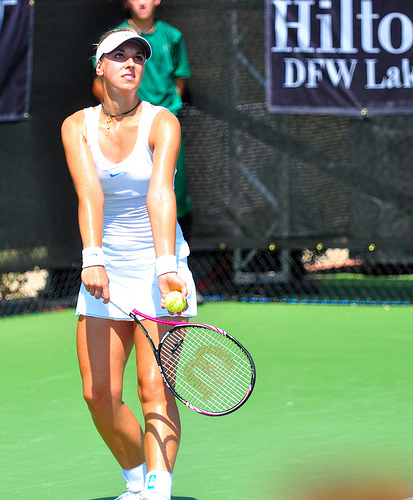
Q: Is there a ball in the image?
A: Yes, there is a ball.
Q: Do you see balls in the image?
A: Yes, there is a ball.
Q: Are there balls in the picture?
A: Yes, there is a ball.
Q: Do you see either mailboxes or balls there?
A: Yes, there is a ball.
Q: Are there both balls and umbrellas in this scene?
A: No, there is a ball but no umbrellas.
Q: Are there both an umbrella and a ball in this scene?
A: No, there is a ball but no umbrellas.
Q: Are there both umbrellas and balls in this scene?
A: No, there is a ball but no umbrellas.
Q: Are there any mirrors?
A: No, there are no mirrors.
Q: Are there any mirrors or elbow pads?
A: No, there are no mirrors or elbow pads.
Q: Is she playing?
A: Yes, the girl is playing.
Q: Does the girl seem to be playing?
A: Yes, the girl is playing.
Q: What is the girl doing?
A: The girl is playing.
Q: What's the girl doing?
A: The girl is playing.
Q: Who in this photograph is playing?
A: The girl is playing.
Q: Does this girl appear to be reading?
A: No, the girl is playing.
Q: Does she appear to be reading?
A: No, the girl is playing.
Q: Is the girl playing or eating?
A: The girl is playing.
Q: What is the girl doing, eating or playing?
A: The girl is playing.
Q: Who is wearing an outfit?
A: The girl is wearing an outfit.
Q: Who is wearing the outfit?
A: The girl is wearing an outfit.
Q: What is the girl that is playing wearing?
A: The girl is wearing an outfit.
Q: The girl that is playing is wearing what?
A: The girl is wearing an outfit.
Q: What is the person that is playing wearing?
A: The girl is wearing an outfit.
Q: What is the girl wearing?
A: The girl is wearing an outfit.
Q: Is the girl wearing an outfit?
A: Yes, the girl is wearing an outfit.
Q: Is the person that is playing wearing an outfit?
A: Yes, the girl is wearing an outfit.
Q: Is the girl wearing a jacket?
A: No, the girl is wearing an outfit.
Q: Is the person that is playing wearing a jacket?
A: No, the girl is wearing an outfit.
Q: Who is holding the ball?
A: The girl is holding the ball.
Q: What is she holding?
A: The girl is holding the ball.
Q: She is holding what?
A: The girl is holding the ball.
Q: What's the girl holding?
A: The girl is holding the ball.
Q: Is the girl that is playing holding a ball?
A: Yes, the girl is holding a ball.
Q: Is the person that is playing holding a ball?
A: Yes, the girl is holding a ball.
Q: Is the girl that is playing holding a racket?
A: No, the girl is holding a ball.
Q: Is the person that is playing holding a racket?
A: No, the girl is holding a ball.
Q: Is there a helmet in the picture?
A: No, there are no helmets.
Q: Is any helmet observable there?
A: No, there are no helmets.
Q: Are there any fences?
A: Yes, there is a fence.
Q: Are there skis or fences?
A: Yes, there is a fence.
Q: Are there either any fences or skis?
A: Yes, there is a fence.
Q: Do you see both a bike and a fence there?
A: No, there is a fence but no bikes.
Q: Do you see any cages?
A: No, there are no cages.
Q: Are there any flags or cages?
A: No, there are no cages or flags.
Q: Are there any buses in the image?
A: No, there are no buses.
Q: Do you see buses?
A: No, there are no buses.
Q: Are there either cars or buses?
A: No, there are no buses or cars.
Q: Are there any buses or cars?
A: No, there are no buses or cars.